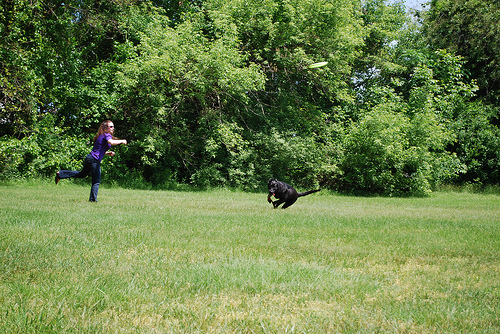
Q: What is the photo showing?
A: It is showing a field.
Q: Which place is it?
A: It is a field.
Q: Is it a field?
A: Yes, it is a field.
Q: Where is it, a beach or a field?
A: It is a field.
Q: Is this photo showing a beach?
A: No, the picture is showing a field.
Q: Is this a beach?
A: No, it is a field.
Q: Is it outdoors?
A: Yes, it is outdoors.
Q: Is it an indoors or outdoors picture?
A: It is outdoors.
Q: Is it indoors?
A: No, it is outdoors.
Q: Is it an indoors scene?
A: No, it is outdoors.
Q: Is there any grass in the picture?
A: Yes, there is grass.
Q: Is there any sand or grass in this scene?
A: Yes, there is grass.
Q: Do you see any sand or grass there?
A: Yes, there is grass.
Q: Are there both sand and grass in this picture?
A: No, there is grass but no sand.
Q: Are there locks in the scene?
A: No, there are no locks.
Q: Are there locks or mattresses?
A: No, there are no locks or mattresses.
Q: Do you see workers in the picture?
A: No, there are no workers.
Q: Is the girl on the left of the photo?
A: Yes, the girl is on the left of the image.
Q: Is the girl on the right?
A: No, the girl is on the left of the image.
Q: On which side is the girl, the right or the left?
A: The girl is on the left of the image.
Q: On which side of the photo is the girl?
A: The girl is on the left of the image.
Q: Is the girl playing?
A: Yes, the girl is playing.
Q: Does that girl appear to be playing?
A: Yes, the girl is playing.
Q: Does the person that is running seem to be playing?
A: Yes, the girl is playing.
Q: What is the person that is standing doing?
A: The girl is playing.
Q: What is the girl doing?
A: The girl is playing.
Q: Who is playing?
A: The girl is playing.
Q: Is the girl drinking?
A: No, the girl is playing.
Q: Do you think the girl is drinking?
A: No, the girl is playing.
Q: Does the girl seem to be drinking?
A: No, the girl is playing.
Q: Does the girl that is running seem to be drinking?
A: No, the girl is playing.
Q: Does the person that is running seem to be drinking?
A: No, the girl is playing.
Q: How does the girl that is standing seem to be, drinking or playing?
A: The girl is playing.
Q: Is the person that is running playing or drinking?
A: The girl is playing.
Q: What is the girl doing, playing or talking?
A: The girl is playing.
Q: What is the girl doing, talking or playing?
A: The girl is playing.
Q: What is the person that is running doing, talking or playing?
A: The girl is playing.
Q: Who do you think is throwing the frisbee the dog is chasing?
A: The girl is throwing the frisbee.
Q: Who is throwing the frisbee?
A: The girl is throwing the frisbee.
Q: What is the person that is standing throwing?
A: The girl is throwing the frisbee.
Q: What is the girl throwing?
A: The girl is throwing the frisbee.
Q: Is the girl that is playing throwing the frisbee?
A: Yes, the girl is throwing the frisbee.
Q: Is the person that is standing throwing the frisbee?
A: Yes, the girl is throwing the frisbee.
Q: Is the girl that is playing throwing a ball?
A: No, the girl is throwing the frisbee.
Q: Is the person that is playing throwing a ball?
A: No, the girl is throwing the frisbee.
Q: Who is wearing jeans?
A: The girl is wearing jeans.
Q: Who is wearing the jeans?
A: The girl is wearing jeans.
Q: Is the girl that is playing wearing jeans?
A: Yes, the girl is wearing jeans.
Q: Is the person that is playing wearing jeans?
A: Yes, the girl is wearing jeans.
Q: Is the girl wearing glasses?
A: No, the girl is wearing jeans.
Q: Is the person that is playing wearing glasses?
A: No, the girl is wearing jeans.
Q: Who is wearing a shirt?
A: The girl is wearing a shirt.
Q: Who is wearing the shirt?
A: The girl is wearing a shirt.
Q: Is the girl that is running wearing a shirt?
A: Yes, the girl is wearing a shirt.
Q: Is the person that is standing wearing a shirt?
A: Yes, the girl is wearing a shirt.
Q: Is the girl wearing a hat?
A: No, the girl is wearing a shirt.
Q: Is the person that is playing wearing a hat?
A: No, the girl is wearing a shirt.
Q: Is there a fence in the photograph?
A: No, there are no fences.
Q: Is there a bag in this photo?
A: No, there are no bags.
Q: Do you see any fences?
A: No, there are no fences.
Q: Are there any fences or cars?
A: No, there are no fences or cars.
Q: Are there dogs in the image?
A: Yes, there is a dog.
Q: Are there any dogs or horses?
A: Yes, there is a dog.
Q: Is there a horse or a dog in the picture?
A: Yes, there is a dog.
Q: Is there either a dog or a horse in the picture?
A: Yes, there is a dog.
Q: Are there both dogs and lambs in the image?
A: No, there is a dog but no lambs.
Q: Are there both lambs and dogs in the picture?
A: No, there is a dog but no lambs.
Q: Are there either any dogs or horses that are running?
A: Yes, the dog is running.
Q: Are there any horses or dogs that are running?
A: Yes, the dog is running.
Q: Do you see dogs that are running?
A: Yes, there is a dog that is running.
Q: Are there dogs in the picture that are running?
A: Yes, there is a dog that is running.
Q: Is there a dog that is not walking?
A: Yes, there is a dog that is running.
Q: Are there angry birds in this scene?
A: No, there are no angry birds.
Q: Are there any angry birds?
A: No, there are no angry birds.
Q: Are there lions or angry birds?
A: No, there are no angry birds or lions.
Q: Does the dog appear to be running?
A: Yes, the dog is running.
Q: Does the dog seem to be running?
A: Yes, the dog is running.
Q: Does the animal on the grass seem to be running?
A: Yes, the dog is running.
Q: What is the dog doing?
A: The dog is running.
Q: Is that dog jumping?
A: No, the dog is running.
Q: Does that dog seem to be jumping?
A: No, the dog is running.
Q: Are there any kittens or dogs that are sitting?
A: No, there is a dog but it is running.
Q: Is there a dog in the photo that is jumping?
A: No, there is a dog but it is running.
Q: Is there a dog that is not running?
A: No, there is a dog but it is running.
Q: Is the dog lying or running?
A: The dog is running.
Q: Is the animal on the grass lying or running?
A: The dog is running.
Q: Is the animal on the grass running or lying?
A: The dog is running.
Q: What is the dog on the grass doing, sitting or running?
A: The dog is running.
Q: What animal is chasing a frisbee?
A: The dog is chasing a frisbee.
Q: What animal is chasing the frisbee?
A: The dog is chasing a frisbee.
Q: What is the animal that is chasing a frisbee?
A: The animal is a dog.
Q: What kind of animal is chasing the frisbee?
A: The animal is a dog.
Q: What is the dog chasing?
A: The dog is chasing a frisbee.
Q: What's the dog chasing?
A: The dog is chasing a frisbee.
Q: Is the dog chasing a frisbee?
A: Yes, the dog is chasing a frisbee.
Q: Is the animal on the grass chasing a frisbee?
A: Yes, the dog is chasing a frisbee.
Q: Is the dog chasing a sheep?
A: No, the dog is chasing a frisbee.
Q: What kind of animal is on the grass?
A: The animal is a dog.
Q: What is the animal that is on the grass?
A: The animal is a dog.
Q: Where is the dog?
A: The dog is on the grass.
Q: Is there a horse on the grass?
A: No, there is a dog on the grass.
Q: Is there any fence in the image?
A: No, there are no fences.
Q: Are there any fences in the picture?
A: No, there are no fences.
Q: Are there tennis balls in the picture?
A: No, there are no tennis balls.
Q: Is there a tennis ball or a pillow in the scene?
A: No, there are no tennis balls or pillows.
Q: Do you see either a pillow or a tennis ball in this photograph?
A: No, there are no tennis balls or pillows.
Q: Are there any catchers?
A: No, there are no catchers.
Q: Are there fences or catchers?
A: No, there are no catchers or fences.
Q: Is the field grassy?
A: Yes, the field is grassy.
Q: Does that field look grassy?
A: Yes, the field is grassy.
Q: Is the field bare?
A: No, the field is grassy.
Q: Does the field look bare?
A: No, the field is grassy.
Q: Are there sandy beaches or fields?
A: No, there is a field but it is grassy.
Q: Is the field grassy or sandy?
A: The field is grassy.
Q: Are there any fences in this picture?
A: No, there are no fences.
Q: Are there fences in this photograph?
A: No, there are no fences.